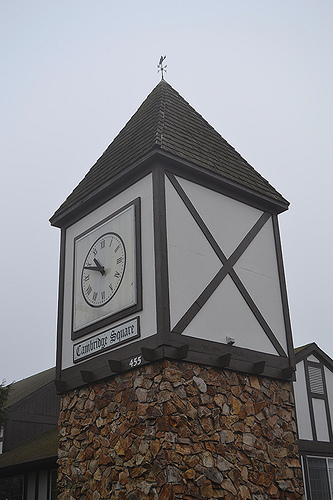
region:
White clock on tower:
[75, 229, 132, 311]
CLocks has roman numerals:
[73, 231, 129, 309]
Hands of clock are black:
[80, 254, 109, 280]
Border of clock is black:
[77, 230, 133, 312]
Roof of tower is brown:
[44, 74, 289, 213]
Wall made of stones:
[46, 366, 303, 498]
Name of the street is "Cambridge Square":
[58, 317, 152, 362]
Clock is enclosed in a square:
[62, 191, 151, 336]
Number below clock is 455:
[123, 348, 145, 372]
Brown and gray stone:
[66, 395, 260, 497]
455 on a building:
[122, 348, 173, 368]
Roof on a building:
[6, 413, 85, 477]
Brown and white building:
[283, 339, 332, 438]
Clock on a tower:
[68, 227, 161, 334]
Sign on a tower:
[64, 316, 151, 351]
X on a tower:
[136, 163, 312, 356]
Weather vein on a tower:
[142, 50, 202, 89]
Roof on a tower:
[73, 75, 287, 184]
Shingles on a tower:
[111, 88, 228, 163]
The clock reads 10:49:
[64, 227, 143, 318]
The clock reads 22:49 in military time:
[63, 222, 154, 317]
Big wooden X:
[160, 162, 303, 350]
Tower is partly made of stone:
[59, 391, 303, 496]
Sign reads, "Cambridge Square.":
[62, 314, 143, 363]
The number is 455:
[119, 347, 148, 373]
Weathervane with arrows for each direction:
[135, 40, 189, 83]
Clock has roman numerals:
[56, 222, 151, 324]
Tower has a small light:
[211, 325, 248, 354]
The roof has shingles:
[14, 68, 323, 222]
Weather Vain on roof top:
[153, 51, 167, 79]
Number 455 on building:
[124, 352, 142, 366]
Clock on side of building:
[75, 227, 132, 310]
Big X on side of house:
[157, 163, 290, 358]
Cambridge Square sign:
[71, 320, 140, 358]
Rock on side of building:
[191, 373, 207, 391]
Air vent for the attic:
[302, 359, 326, 396]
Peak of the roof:
[294, 339, 329, 369]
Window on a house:
[303, 453, 329, 495]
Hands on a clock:
[83, 256, 107, 280]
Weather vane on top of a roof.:
[156, 56, 166, 80]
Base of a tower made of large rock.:
[55, 356, 309, 499]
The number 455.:
[127, 356, 143, 367]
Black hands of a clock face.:
[81, 259, 107, 278]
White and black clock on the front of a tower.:
[79, 231, 126, 309]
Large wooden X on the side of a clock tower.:
[162, 171, 288, 358]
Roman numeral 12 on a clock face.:
[98, 240, 107, 249]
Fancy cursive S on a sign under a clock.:
[108, 329, 119, 347]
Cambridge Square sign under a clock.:
[70, 314, 142, 367]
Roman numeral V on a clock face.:
[107, 281, 114, 292]